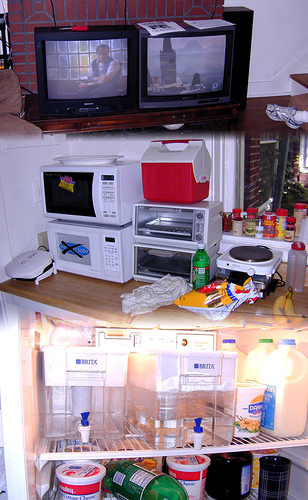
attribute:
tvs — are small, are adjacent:
[14, 9, 266, 159]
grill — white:
[1, 239, 63, 287]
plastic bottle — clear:
[285, 239, 307, 292]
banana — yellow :
[263, 285, 288, 343]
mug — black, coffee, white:
[257, 455, 292, 498]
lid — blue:
[274, 340, 297, 349]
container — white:
[226, 368, 289, 457]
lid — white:
[139, 135, 215, 182]